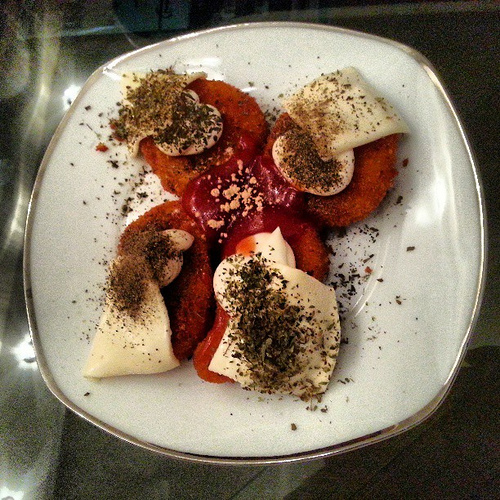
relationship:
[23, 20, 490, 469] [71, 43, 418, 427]
plate has food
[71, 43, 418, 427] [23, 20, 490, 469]
food on plate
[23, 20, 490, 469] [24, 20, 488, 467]
plate has trim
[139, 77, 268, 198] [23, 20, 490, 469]
carrot on plate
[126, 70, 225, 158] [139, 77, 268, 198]
cheese over carrot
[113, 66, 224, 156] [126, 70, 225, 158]
spices over cheese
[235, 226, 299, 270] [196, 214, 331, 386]
cream over carrot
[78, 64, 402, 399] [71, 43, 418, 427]
spices over food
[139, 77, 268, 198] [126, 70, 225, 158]
carrot under cheese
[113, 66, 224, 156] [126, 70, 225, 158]
spices on cheese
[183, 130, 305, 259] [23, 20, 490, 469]
sauce in plate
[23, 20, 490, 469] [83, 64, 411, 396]
plate has cheese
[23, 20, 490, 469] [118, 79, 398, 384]
plate has carrots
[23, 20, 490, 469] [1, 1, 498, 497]
plate on top of table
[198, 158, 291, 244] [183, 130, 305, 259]
cheese over sauce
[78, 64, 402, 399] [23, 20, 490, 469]
spices on plate